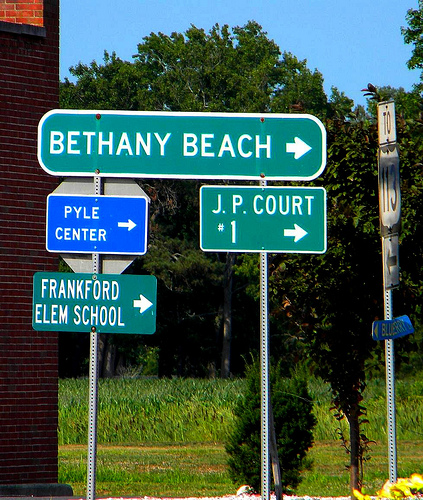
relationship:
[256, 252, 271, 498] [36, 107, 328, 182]
post holding up sign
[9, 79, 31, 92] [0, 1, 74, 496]
bricks on building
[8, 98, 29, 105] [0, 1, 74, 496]
bricks on building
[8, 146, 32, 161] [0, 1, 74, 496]
bricks on building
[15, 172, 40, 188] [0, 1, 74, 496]
bricks on building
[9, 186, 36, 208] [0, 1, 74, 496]
bricks on building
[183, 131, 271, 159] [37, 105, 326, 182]
beach on sign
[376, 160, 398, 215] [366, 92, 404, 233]
113 on sign